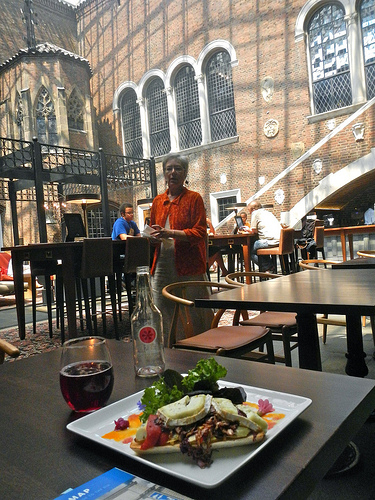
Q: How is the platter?
A: Square.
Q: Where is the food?
A: Platter.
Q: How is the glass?
A: Almost full.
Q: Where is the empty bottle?
A: The table.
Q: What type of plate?
A: Rectangle.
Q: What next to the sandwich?
A: Lettuce.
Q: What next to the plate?
A: Glass cup.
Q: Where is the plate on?
A: Table.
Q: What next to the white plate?
A: Book.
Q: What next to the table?
A: Chairs.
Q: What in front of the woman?
A: Empty bottle.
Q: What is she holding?
A: Paper.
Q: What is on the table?
A: Food.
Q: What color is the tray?
A: White.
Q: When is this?
A: Daytime.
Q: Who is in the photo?
A: People.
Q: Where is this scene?
A: At a restaurant.